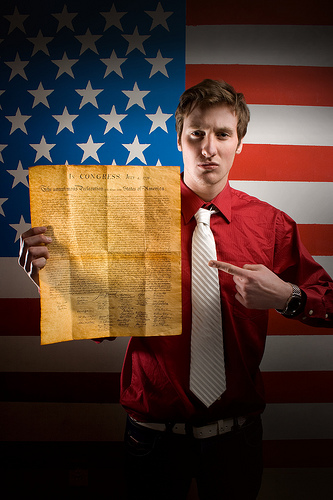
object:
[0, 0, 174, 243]
stars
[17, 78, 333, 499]
man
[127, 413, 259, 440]
belt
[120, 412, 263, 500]
jeans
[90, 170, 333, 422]
shirt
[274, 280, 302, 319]
watch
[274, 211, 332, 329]
arm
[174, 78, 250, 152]
hair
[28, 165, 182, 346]
paper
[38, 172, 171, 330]
writing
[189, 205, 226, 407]
tie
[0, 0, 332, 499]
stripes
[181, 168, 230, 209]
neck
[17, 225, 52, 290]
right hand